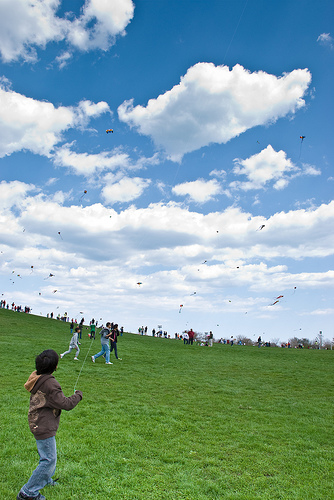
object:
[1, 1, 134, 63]
cloud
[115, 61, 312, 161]
cloud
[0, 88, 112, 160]
cloud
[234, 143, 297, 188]
cloud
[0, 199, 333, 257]
cloud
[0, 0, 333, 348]
formation